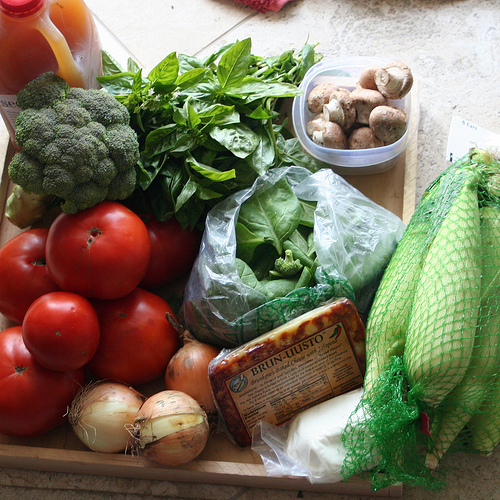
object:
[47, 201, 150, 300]
tomato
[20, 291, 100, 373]
tomato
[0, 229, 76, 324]
tomato